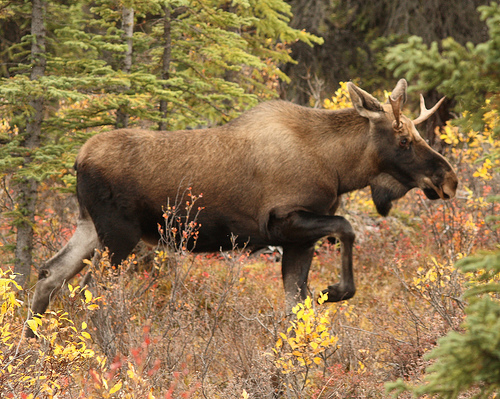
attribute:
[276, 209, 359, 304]
leg — bent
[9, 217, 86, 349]
rear leg — gray, bent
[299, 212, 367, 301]
moose's leg — bent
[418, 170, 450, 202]
mouth — closed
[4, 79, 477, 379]
moose — white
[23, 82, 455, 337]
moose — brown, large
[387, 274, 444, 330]
grass — short, green, brown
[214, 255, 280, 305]
grass — brown, green, short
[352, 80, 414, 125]
ears — upright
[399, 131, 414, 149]
eye — open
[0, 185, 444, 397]
leaves — red, yellow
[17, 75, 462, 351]
moose — brown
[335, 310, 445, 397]
grass — brown, green, short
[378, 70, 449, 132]
moose antlers — small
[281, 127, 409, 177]
fur — brown, dark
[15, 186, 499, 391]
grass — brown, green, short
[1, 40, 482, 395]
area — wooded